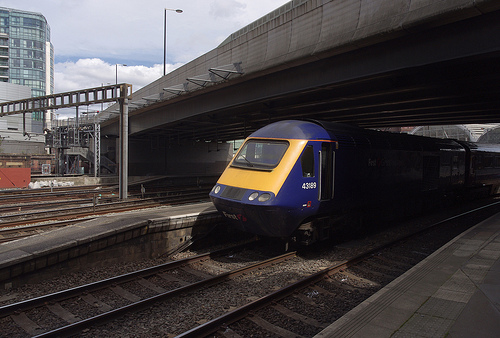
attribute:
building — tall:
[4, 7, 59, 157]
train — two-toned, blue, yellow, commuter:
[205, 116, 497, 268]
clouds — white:
[43, 50, 179, 123]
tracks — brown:
[4, 185, 498, 334]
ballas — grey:
[47, 196, 497, 336]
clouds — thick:
[1, 1, 290, 59]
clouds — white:
[50, 53, 181, 121]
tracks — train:
[2, 229, 307, 334]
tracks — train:
[181, 200, 498, 330]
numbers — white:
[301, 177, 320, 192]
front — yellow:
[205, 127, 306, 225]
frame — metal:
[5, 83, 135, 209]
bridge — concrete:
[58, 1, 495, 167]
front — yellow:
[205, 122, 300, 243]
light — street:
[171, 7, 181, 16]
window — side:
[299, 147, 315, 179]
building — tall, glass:
[2, 4, 56, 138]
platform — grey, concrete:
[312, 201, 495, 333]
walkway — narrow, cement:
[1, 199, 230, 267]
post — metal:
[114, 81, 136, 198]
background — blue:
[287, 172, 325, 202]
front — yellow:
[211, 135, 305, 196]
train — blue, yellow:
[192, 106, 498, 243]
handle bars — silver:
[307, 146, 333, 209]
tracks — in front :
[18, 236, 185, 336]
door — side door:
[317, 134, 338, 214]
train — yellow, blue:
[200, 106, 390, 254]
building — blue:
[3, 5, 99, 164]